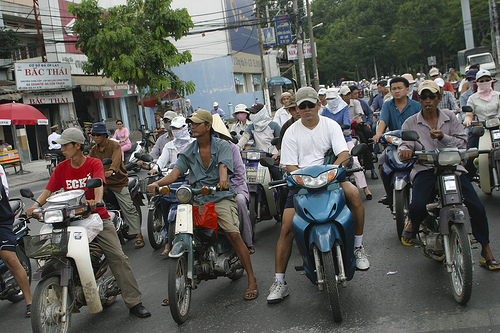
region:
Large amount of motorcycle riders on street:
[0, 8, 497, 320]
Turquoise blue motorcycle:
[265, 145, 371, 310]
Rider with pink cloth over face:
[468, 68, 498, 112]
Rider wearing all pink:
[113, 120, 132, 167]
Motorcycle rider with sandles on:
[150, 280, 263, 311]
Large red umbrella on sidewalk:
[0, 98, 52, 158]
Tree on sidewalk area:
[56, 0, 208, 137]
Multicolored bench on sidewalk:
[0, 148, 32, 178]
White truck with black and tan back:
[452, 41, 499, 82]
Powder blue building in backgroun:
[149, 53, 281, 145]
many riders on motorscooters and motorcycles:
[2, 58, 492, 330]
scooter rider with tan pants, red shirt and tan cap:
[22, 130, 152, 320]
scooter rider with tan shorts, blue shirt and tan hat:
[141, 108, 259, 327]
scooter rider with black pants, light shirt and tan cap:
[391, 79, 496, 304]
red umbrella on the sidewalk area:
[0, 96, 52, 174]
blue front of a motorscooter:
[285, 162, 357, 277]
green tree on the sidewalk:
[65, 0, 195, 126]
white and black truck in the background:
[455, 43, 497, 84]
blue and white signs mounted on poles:
[273, 20, 322, 67]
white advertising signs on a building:
[14, 51, 76, 108]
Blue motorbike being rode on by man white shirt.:
[268, 165, 363, 322]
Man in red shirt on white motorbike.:
[29, 125, 153, 332]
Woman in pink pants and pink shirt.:
[108, 109, 138, 161]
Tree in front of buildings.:
[66, 0, 197, 140]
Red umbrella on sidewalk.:
[1, 99, 51, 148]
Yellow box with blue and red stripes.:
[0, 148, 22, 163]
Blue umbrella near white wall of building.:
[265, 70, 290, 89]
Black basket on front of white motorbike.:
[19, 220, 71, 260]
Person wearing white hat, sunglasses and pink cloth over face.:
[460, 68, 499, 130]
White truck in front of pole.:
[454, 45, 496, 77]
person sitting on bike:
[148, 111, 263, 304]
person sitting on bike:
[21, 127, 153, 317]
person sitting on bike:
[260, 79, 374, 304]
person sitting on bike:
[392, 77, 496, 272]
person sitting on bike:
[81, 123, 146, 248]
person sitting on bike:
[142, 115, 190, 195]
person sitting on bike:
[228, 101, 282, 173]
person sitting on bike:
[371, 77, 421, 137]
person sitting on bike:
[317, 87, 327, 107]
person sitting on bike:
[106, 116, 132, 159]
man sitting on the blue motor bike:
[266, 87, 371, 304]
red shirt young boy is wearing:
[43, 155, 109, 222]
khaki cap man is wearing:
[416, 78, 441, 96]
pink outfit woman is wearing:
[112, 127, 131, 162]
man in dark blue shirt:
[378, 99, 419, 129]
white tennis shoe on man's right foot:
[266, 279, 289, 304]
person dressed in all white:
[151, 117, 196, 177]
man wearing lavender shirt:
[401, 109, 468, 162]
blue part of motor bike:
[293, 165, 350, 253]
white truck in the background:
[466, 52, 496, 87]